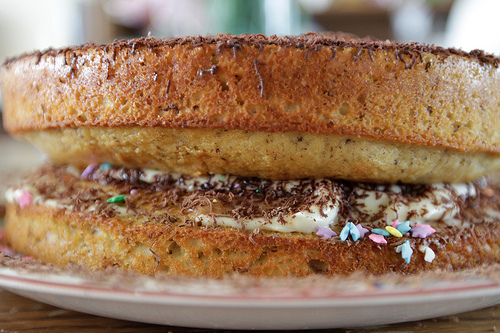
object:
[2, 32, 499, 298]
cake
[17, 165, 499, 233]
whipped cream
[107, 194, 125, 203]
sprinkles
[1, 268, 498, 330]
plate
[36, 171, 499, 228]
shavings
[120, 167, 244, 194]
frosting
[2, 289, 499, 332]
table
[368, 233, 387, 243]
star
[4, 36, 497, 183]
bread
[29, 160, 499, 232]
filling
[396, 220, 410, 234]
flakes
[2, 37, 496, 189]
layer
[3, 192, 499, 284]
bottom